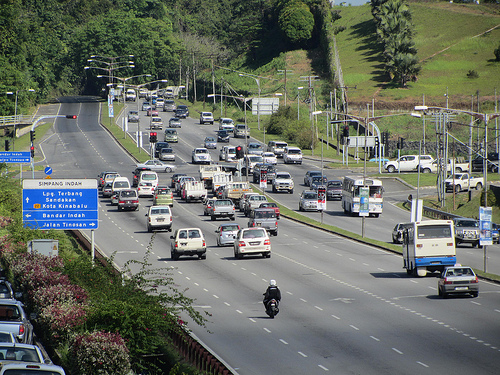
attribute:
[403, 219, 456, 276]
truck — blue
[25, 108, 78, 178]
light — red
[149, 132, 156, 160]
signal — black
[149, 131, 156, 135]
light — red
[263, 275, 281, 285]
helmet — white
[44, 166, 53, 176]
sign — blue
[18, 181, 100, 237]
sign — blue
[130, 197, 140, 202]
light — red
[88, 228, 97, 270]
pole — thin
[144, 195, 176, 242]
car — white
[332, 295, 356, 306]
arrow — white , faded , directional 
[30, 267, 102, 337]
bush — red, low, green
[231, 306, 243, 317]
line — white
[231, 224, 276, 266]
suv — white 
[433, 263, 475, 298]
car — small, white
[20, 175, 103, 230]
blue/white sign — blue and white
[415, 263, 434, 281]
flap — rear , white 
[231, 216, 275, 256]
jeep — White 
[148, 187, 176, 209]
jeep — Green 